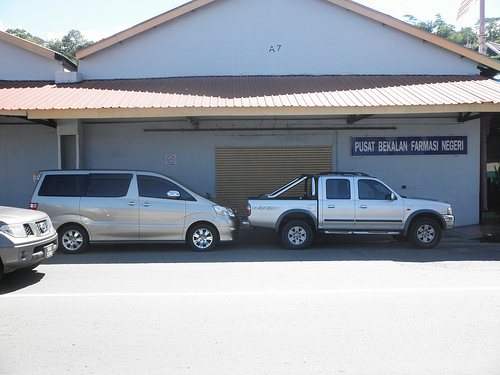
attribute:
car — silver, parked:
[16, 162, 238, 255]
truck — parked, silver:
[241, 144, 464, 264]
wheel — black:
[407, 210, 446, 247]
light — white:
[444, 207, 455, 217]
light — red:
[242, 202, 255, 216]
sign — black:
[343, 130, 476, 158]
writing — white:
[354, 136, 467, 153]